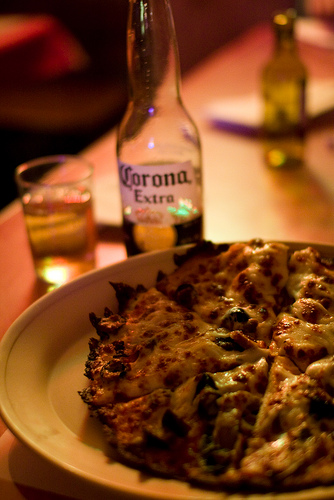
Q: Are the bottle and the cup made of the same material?
A: Yes, both the bottle and the cup are made of glass.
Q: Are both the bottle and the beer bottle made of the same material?
A: Yes, both the bottle and the beer bottle are made of glass.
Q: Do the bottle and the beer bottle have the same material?
A: Yes, both the bottle and the beer bottle are made of glass.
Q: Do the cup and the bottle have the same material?
A: Yes, both the cup and the bottle are made of glass.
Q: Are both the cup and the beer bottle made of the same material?
A: Yes, both the cup and the beer bottle are made of glass.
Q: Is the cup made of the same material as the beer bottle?
A: Yes, both the cup and the beer bottle are made of glass.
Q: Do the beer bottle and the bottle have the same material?
A: Yes, both the beer bottle and the bottle are made of glass.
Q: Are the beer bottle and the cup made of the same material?
A: Yes, both the beer bottle and the cup are made of glass.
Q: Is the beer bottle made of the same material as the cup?
A: Yes, both the beer bottle and the cup are made of glass.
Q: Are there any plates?
A: Yes, there is a plate.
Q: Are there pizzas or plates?
A: Yes, there is a plate.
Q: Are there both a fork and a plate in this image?
A: No, there is a plate but no forks.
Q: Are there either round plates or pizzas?
A: Yes, there is a round plate.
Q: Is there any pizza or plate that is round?
A: Yes, the plate is round.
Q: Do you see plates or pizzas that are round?
A: Yes, the plate is round.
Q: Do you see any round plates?
A: Yes, there is a round plate.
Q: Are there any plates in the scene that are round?
A: Yes, there is a plate that is round.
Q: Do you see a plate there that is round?
A: Yes, there is a plate that is round.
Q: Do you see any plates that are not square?
A: Yes, there is a round plate.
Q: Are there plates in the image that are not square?
A: Yes, there is a round plate.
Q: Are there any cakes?
A: No, there are no cakes.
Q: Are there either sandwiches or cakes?
A: No, there are no cakes or sandwiches.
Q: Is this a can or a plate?
A: This is a plate.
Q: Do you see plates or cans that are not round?
A: No, there is a plate but it is round.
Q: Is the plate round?
A: Yes, the plate is round.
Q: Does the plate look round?
A: Yes, the plate is round.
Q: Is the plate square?
A: No, the plate is round.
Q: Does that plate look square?
A: No, the plate is round.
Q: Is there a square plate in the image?
A: No, there is a plate but it is round.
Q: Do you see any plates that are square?
A: No, there is a plate but it is round.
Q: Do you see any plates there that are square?
A: No, there is a plate but it is round.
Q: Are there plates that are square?
A: No, there is a plate but it is round.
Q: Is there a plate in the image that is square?
A: No, there is a plate but it is round.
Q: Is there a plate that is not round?
A: No, there is a plate but it is round.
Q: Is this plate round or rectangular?
A: The plate is round.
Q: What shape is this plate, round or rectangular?
A: The plate is round.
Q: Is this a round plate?
A: Yes, this is a round plate.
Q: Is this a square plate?
A: No, this is a round plate.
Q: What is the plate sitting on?
A: The plate is sitting on the counter.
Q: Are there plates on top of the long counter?
A: Yes, there is a plate on top of the counter.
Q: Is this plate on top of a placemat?
A: No, the plate is on top of the counter.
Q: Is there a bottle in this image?
A: Yes, there is a bottle.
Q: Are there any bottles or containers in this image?
A: Yes, there is a bottle.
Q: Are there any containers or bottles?
A: Yes, there is a bottle.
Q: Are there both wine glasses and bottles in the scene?
A: No, there is a bottle but no wine glasses.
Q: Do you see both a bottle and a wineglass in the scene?
A: No, there is a bottle but no wine glasses.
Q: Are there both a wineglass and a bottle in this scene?
A: No, there is a bottle but no wine glasses.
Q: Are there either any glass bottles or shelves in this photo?
A: Yes, there is a glass bottle.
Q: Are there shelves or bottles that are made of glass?
A: Yes, the bottle is made of glass.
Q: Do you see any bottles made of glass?
A: Yes, there is a bottle that is made of glass.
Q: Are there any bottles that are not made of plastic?
A: Yes, there is a bottle that is made of glass.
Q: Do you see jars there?
A: No, there are no jars.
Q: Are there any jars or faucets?
A: No, there are no jars or faucets.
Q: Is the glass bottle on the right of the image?
A: Yes, the bottle is on the right of the image.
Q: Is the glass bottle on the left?
A: No, the bottle is on the right of the image.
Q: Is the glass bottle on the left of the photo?
A: No, the bottle is on the right of the image.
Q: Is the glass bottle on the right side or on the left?
A: The bottle is on the right of the image.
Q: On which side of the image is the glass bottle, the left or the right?
A: The bottle is on the right of the image.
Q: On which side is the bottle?
A: The bottle is on the right of the image.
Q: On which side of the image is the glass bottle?
A: The bottle is on the right of the image.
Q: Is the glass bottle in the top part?
A: Yes, the bottle is in the top of the image.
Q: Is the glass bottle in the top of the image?
A: Yes, the bottle is in the top of the image.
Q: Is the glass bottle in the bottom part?
A: No, the bottle is in the top of the image.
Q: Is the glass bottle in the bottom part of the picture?
A: No, the bottle is in the top of the image.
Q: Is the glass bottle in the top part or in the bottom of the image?
A: The bottle is in the top of the image.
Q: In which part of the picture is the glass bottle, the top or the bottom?
A: The bottle is in the top of the image.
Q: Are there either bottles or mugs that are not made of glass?
A: No, there is a bottle but it is made of glass.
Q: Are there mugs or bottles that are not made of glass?
A: No, there is a bottle but it is made of glass.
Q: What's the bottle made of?
A: The bottle is made of glass.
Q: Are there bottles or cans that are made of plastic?
A: No, there is a bottle but it is made of glass.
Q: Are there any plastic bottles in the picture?
A: No, there is a bottle but it is made of glass.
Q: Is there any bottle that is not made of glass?
A: No, there is a bottle but it is made of glass.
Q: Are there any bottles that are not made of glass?
A: No, there is a bottle but it is made of glass.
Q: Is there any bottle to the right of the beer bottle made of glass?
A: Yes, there is a bottle to the right of the beer bottle.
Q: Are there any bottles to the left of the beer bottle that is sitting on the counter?
A: No, the bottle is to the right of the beer bottle.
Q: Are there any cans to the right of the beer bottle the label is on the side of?
A: No, there is a bottle to the right of the beer bottle.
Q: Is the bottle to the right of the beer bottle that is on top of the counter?
A: Yes, the bottle is to the right of the beer bottle.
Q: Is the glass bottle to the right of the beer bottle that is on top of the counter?
A: Yes, the bottle is to the right of the beer bottle.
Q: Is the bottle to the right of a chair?
A: No, the bottle is to the right of the beer bottle.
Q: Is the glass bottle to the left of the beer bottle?
A: No, the bottle is to the right of the beer bottle.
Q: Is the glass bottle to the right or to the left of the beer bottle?
A: The bottle is to the right of the beer bottle.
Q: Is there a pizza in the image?
A: Yes, there is a pizza.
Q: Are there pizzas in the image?
A: Yes, there is a pizza.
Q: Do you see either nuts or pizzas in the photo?
A: Yes, there is a pizza.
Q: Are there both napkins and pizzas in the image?
A: No, there is a pizza but no napkins.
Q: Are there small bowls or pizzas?
A: Yes, there is a small pizza.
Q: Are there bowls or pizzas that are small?
A: Yes, the pizza is small.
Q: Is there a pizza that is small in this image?
A: Yes, there is a small pizza.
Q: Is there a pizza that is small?
A: Yes, there is a pizza that is small.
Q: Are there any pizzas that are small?
A: Yes, there is a pizza that is small.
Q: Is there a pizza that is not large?
A: Yes, there is a small pizza.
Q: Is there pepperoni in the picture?
A: No, there is no pepperoni.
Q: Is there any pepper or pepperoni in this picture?
A: No, there are no pepperoni or peppers.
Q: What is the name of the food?
A: The food is a pizza.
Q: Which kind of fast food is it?
A: The food is a pizza.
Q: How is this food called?
A: This is a pizza.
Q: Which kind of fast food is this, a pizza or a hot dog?
A: This is a pizza.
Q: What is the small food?
A: The food is a pizza.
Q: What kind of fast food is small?
A: The fast food is a pizza.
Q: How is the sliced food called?
A: The food is a pizza.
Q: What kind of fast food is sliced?
A: The fast food is a pizza.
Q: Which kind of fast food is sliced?
A: The fast food is a pizza.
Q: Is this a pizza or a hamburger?
A: This is a pizza.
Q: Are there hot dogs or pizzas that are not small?
A: No, there is a pizza but it is small.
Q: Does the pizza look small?
A: Yes, the pizza is small.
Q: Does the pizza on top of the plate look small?
A: Yes, the pizza is small.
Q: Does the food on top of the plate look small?
A: Yes, the pizza is small.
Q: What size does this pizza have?
A: The pizza has small size.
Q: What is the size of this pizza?
A: The pizza is small.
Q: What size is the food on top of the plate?
A: The pizza is small.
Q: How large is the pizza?
A: The pizza is small.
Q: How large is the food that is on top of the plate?
A: The pizza is small.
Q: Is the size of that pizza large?
A: No, the pizza is small.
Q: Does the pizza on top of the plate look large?
A: No, the pizza is small.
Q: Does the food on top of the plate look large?
A: No, the pizza is small.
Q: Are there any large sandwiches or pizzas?
A: No, there is a pizza but it is small.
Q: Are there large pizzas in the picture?
A: No, there is a pizza but it is small.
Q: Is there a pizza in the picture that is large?
A: No, there is a pizza but it is small.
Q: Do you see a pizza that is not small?
A: No, there is a pizza but it is small.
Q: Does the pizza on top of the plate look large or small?
A: The pizza is small.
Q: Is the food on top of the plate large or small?
A: The pizza is small.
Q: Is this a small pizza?
A: Yes, this is a small pizza.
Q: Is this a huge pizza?
A: No, this is a small pizza.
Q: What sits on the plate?
A: The pizza sits on the plate.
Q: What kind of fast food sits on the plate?
A: The food is a pizza.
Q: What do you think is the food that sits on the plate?
A: The food is a pizza.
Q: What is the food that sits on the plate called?
A: The food is a pizza.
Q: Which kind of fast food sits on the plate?
A: The food is a pizza.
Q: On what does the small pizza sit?
A: The pizza sits on the plate.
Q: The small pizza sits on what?
A: The pizza sits on the plate.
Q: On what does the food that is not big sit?
A: The pizza sits on the plate.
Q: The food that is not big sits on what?
A: The pizza sits on the plate.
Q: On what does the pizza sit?
A: The pizza sits on the plate.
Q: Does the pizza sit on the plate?
A: Yes, the pizza sits on the plate.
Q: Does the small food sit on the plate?
A: Yes, the pizza sits on the plate.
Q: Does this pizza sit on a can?
A: No, the pizza sits on the plate.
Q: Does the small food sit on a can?
A: No, the pizza sits on the plate.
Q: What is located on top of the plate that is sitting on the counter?
A: The pizza is on top of the plate.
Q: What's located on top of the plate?
A: The pizza is on top of the plate.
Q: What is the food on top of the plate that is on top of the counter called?
A: The food is a pizza.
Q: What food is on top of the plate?
A: The food is a pizza.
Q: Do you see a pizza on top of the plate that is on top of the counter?
A: Yes, there is a pizza on top of the plate.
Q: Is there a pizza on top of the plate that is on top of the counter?
A: Yes, there is a pizza on top of the plate.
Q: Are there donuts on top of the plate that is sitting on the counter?
A: No, there is a pizza on top of the plate.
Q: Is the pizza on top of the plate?
A: Yes, the pizza is on top of the plate.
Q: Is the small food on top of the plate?
A: Yes, the pizza is on top of the plate.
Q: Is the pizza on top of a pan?
A: No, the pizza is on top of the plate.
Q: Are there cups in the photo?
A: Yes, there is a cup.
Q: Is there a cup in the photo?
A: Yes, there is a cup.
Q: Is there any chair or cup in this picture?
A: Yes, there is a cup.